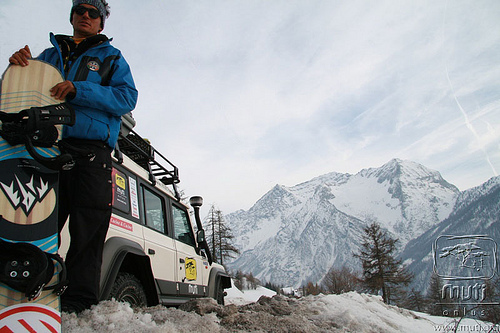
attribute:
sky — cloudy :
[0, 0, 499, 214]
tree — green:
[358, 227, 413, 314]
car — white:
[111, 132, 246, 312]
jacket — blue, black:
[35, 28, 140, 152]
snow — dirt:
[66, 274, 495, 331]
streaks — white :
[451, 97, 485, 154]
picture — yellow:
[177, 253, 200, 285]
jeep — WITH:
[97, 109, 237, 313]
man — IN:
[24, 8, 179, 311]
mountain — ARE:
[400, 180, 496, 312]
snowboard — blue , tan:
[3, 48, 71, 330]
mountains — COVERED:
[210, 158, 497, 315]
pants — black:
[47, 134, 117, 319]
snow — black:
[234, 277, 372, 330]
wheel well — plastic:
[111, 265, 157, 312]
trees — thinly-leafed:
[198, 200, 242, 283]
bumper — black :
[188, 262, 241, 287]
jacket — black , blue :
[54, 39, 146, 136]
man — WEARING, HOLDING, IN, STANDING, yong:
[9, 0, 135, 309]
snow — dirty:
[232, 290, 402, 331]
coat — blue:
[32, 31, 140, 150]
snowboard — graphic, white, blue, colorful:
[2, 57, 67, 331]